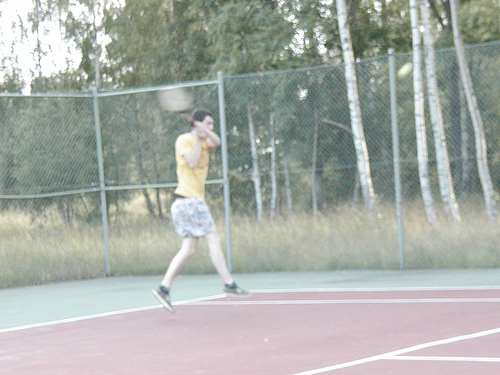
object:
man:
[151, 104, 251, 313]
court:
[1, 265, 498, 372]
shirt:
[176, 131, 211, 199]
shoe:
[153, 284, 176, 316]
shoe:
[222, 284, 253, 299]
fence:
[0, 39, 499, 290]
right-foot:
[219, 279, 253, 302]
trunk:
[334, 1, 377, 214]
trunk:
[409, 1, 437, 227]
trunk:
[417, 0, 458, 226]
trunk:
[447, 1, 496, 216]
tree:
[444, 3, 496, 244]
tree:
[28, 73, 117, 233]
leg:
[143, 199, 199, 313]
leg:
[193, 198, 248, 299]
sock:
[159, 282, 169, 293]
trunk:
[245, 103, 263, 218]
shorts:
[167, 199, 215, 235]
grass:
[0, 195, 500, 290]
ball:
[397, 60, 414, 79]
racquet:
[158, 82, 195, 125]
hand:
[193, 122, 211, 134]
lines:
[291, 327, 499, 374]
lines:
[176, 298, 497, 304]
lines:
[0, 290, 229, 332]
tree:
[271, 0, 393, 216]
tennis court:
[0, 36, 500, 368]